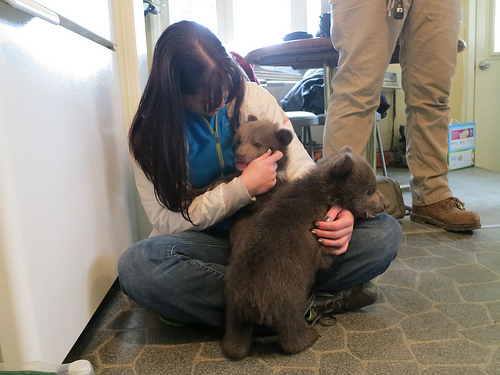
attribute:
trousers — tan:
[323, 0, 463, 209]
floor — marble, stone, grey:
[63, 157, 500, 374]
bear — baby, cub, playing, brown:
[217, 143, 391, 360]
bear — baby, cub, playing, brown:
[192, 115, 295, 268]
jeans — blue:
[117, 205, 405, 332]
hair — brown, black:
[127, 20, 248, 229]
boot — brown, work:
[410, 197, 482, 233]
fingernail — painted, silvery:
[311, 229, 319, 238]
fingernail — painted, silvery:
[324, 215, 331, 224]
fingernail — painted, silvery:
[314, 221, 320, 228]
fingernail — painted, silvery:
[318, 239, 324, 246]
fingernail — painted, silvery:
[331, 251, 335, 257]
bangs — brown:
[201, 60, 246, 113]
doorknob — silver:
[477, 59, 490, 72]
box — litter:
[446, 117, 477, 173]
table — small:
[243, 33, 465, 71]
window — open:
[168, 0, 322, 60]